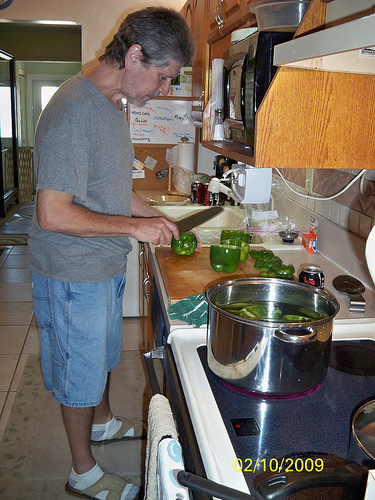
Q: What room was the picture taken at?
A: It was taken at the kitchen.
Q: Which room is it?
A: It is a kitchen.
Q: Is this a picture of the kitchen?
A: Yes, it is showing the kitchen.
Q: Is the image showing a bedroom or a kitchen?
A: It is showing a kitchen.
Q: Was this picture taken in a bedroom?
A: No, the picture was taken in a kitchen.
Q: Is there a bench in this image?
A: No, there are no benches.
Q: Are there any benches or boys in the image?
A: No, there are no benches or boys.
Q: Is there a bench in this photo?
A: No, there are no benches.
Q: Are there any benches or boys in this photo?
A: No, there are no benches or boys.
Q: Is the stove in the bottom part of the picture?
A: Yes, the stove is in the bottom of the image.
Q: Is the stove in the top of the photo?
A: No, the stove is in the bottom of the image.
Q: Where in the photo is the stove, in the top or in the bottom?
A: The stove is in the bottom of the image.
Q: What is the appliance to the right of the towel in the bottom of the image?
A: The appliance is a stove.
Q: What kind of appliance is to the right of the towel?
A: The appliance is a stove.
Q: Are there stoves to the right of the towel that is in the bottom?
A: Yes, there is a stove to the right of the towel.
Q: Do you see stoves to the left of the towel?
A: No, the stove is to the right of the towel.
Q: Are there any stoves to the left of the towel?
A: No, the stove is to the right of the towel.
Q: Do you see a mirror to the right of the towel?
A: No, there is a stove to the right of the towel.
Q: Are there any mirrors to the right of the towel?
A: No, there is a stove to the right of the towel.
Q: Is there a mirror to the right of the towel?
A: No, there is a stove to the right of the towel.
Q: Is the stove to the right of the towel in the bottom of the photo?
A: Yes, the stove is to the right of the towel.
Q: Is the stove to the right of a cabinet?
A: No, the stove is to the right of the towel.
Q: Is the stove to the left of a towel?
A: No, the stove is to the right of a towel.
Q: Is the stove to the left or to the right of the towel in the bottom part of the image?
A: The stove is to the right of the towel.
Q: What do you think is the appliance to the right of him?
A: The appliance is a stove.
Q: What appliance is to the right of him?
A: The appliance is a stove.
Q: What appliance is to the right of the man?
A: The appliance is a stove.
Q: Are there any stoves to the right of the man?
A: Yes, there is a stove to the right of the man.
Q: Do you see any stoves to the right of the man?
A: Yes, there is a stove to the right of the man.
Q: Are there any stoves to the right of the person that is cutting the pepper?
A: Yes, there is a stove to the right of the man.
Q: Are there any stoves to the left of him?
A: No, the stove is to the right of the man.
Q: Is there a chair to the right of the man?
A: No, there is a stove to the right of the man.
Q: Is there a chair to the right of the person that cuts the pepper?
A: No, there is a stove to the right of the man.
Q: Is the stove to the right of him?
A: Yes, the stove is to the right of the man.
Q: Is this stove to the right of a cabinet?
A: No, the stove is to the right of the man.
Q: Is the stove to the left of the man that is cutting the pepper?
A: No, the stove is to the right of the man.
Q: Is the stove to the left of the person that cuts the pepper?
A: No, the stove is to the right of the man.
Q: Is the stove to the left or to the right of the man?
A: The stove is to the right of the man.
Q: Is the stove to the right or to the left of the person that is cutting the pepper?
A: The stove is to the right of the man.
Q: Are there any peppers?
A: Yes, there is a pepper.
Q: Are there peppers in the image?
A: Yes, there is a pepper.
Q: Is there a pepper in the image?
A: Yes, there is a pepper.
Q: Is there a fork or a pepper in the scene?
A: Yes, there is a pepper.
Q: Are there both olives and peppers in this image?
A: No, there is a pepper but no olives.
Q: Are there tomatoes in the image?
A: No, there are no tomatoes.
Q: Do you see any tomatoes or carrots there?
A: No, there are no tomatoes or carrots.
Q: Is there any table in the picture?
A: No, there are no tables.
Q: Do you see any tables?
A: No, there are no tables.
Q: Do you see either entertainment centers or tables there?
A: No, there are no tables or entertainment centers.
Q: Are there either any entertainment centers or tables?
A: No, there are no tables or entertainment centers.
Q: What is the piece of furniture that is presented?
A: The piece of furniture is a shelf.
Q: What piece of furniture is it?
A: The piece of furniture is a shelf.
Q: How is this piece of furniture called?
A: This is a shelf.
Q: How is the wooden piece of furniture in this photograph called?
A: The piece of furniture is a shelf.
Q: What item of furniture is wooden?
A: The piece of furniture is a shelf.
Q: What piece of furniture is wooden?
A: The piece of furniture is a shelf.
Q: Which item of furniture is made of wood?
A: The piece of furniture is a shelf.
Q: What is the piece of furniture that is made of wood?
A: The piece of furniture is a shelf.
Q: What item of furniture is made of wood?
A: The piece of furniture is a shelf.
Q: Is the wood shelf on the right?
A: Yes, the shelf is on the right of the image.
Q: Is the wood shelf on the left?
A: No, the shelf is on the right of the image.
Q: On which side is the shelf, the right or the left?
A: The shelf is on the right of the image.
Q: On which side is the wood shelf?
A: The shelf is on the right of the image.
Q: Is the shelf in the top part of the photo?
A: Yes, the shelf is in the top of the image.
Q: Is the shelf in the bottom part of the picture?
A: No, the shelf is in the top of the image.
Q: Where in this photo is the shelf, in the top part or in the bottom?
A: The shelf is in the top of the image.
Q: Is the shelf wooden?
A: Yes, the shelf is wooden.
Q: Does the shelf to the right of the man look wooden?
A: Yes, the shelf is wooden.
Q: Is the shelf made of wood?
A: Yes, the shelf is made of wood.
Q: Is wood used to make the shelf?
A: Yes, the shelf is made of wood.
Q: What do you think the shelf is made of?
A: The shelf is made of wood.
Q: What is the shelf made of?
A: The shelf is made of wood.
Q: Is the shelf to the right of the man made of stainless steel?
A: No, the shelf is made of wood.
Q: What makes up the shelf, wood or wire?
A: The shelf is made of wood.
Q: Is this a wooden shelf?
A: Yes, this is a wooden shelf.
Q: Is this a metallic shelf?
A: No, this is a wooden shelf.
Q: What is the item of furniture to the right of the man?
A: The piece of furniture is a shelf.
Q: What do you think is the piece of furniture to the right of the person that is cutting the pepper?
A: The piece of furniture is a shelf.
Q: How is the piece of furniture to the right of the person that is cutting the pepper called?
A: The piece of furniture is a shelf.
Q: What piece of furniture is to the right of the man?
A: The piece of furniture is a shelf.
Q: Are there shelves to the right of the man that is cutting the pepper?
A: Yes, there is a shelf to the right of the man.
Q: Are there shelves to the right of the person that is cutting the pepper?
A: Yes, there is a shelf to the right of the man.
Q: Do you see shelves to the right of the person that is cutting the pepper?
A: Yes, there is a shelf to the right of the man.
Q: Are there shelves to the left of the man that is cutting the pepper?
A: No, the shelf is to the right of the man.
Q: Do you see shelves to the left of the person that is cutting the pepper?
A: No, the shelf is to the right of the man.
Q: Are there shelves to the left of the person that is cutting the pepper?
A: No, the shelf is to the right of the man.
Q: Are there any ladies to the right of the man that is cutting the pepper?
A: No, there is a shelf to the right of the man.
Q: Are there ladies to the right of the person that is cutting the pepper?
A: No, there is a shelf to the right of the man.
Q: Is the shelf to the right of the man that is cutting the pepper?
A: Yes, the shelf is to the right of the man.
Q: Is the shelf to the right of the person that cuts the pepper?
A: Yes, the shelf is to the right of the man.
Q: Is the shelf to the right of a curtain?
A: No, the shelf is to the right of the man.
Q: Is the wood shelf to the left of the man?
A: No, the shelf is to the right of the man.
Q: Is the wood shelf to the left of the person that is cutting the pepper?
A: No, the shelf is to the right of the man.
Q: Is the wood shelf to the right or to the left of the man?
A: The shelf is to the right of the man.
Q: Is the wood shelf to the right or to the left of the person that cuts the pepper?
A: The shelf is to the right of the man.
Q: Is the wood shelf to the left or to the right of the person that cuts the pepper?
A: The shelf is to the right of the man.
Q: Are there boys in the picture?
A: No, there are no boys.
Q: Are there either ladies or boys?
A: No, there are no boys or ladies.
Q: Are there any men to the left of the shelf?
A: Yes, there is a man to the left of the shelf.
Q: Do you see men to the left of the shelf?
A: Yes, there is a man to the left of the shelf.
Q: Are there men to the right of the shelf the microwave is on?
A: No, the man is to the left of the shelf.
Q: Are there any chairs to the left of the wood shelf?
A: No, there is a man to the left of the shelf.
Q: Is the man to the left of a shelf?
A: Yes, the man is to the left of a shelf.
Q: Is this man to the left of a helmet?
A: No, the man is to the left of a shelf.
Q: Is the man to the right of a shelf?
A: No, the man is to the left of a shelf.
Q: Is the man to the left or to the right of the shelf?
A: The man is to the left of the shelf.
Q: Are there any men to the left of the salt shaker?
A: Yes, there is a man to the left of the salt shaker.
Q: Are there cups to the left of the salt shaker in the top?
A: No, there is a man to the left of the salt shaker.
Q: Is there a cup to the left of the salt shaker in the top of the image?
A: No, there is a man to the left of the salt shaker.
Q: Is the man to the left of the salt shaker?
A: Yes, the man is to the left of the salt shaker.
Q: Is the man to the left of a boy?
A: No, the man is to the left of the salt shaker.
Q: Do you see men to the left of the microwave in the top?
A: Yes, there is a man to the left of the microwave.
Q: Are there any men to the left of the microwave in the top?
A: Yes, there is a man to the left of the microwave.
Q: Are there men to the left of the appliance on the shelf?
A: Yes, there is a man to the left of the microwave.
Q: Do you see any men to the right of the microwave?
A: No, the man is to the left of the microwave.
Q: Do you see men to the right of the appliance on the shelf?
A: No, the man is to the left of the microwave.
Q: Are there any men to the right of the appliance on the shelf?
A: No, the man is to the left of the microwave.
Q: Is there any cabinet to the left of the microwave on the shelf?
A: No, there is a man to the left of the microwave.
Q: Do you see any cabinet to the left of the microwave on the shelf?
A: No, there is a man to the left of the microwave.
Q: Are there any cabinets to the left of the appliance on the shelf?
A: No, there is a man to the left of the microwave.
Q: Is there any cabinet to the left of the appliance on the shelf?
A: No, there is a man to the left of the microwave.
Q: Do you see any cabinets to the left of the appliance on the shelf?
A: No, there is a man to the left of the microwave.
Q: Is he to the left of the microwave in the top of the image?
A: Yes, the man is to the left of the microwave.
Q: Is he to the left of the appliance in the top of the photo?
A: Yes, the man is to the left of the microwave.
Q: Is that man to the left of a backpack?
A: No, the man is to the left of the microwave.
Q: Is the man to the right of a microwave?
A: No, the man is to the left of a microwave.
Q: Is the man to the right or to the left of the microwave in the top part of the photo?
A: The man is to the left of the microwave.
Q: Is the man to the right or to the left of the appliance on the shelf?
A: The man is to the left of the microwave.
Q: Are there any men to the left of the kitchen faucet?
A: Yes, there is a man to the left of the tap.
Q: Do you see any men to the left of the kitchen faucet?
A: Yes, there is a man to the left of the tap.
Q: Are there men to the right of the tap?
A: No, the man is to the left of the tap.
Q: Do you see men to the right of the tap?
A: No, the man is to the left of the tap.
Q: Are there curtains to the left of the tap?
A: No, there is a man to the left of the tap.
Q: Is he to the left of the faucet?
A: Yes, the man is to the left of the faucet.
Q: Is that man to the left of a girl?
A: No, the man is to the left of the faucet.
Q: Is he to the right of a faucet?
A: No, the man is to the left of a faucet.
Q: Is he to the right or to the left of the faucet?
A: The man is to the left of the faucet.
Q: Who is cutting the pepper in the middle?
A: The man is cutting the pepper.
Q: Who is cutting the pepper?
A: The man is cutting the pepper.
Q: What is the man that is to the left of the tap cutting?
A: The man is cutting the pepper.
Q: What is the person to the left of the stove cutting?
A: The man is cutting the pepper.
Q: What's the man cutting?
A: The man is cutting the pepper.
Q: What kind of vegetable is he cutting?
A: The man is cutting the pepper.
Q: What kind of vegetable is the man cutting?
A: The man is cutting the pepper.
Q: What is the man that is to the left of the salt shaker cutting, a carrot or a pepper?
A: The man is cutting a pepper.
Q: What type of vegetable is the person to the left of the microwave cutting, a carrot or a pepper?
A: The man is cutting a pepper.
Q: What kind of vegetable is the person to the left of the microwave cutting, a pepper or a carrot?
A: The man is cutting a pepper.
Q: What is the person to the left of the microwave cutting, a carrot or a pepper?
A: The man is cutting a pepper.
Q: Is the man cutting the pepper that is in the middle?
A: Yes, the man is cutting the pepper.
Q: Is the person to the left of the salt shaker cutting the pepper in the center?
A: Yes, the man is cutting the pepper.